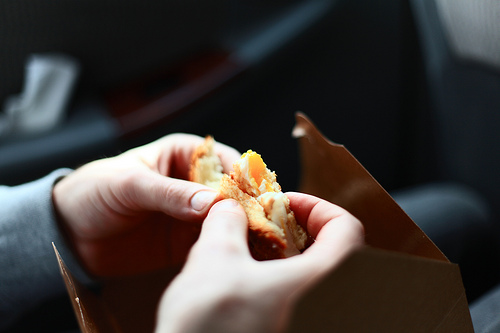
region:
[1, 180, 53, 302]
sleeve for long sleeve shirt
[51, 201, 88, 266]
shadow of sleeve and curved palm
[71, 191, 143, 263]
palm of hand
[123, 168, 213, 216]
thumb that is straight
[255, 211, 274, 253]
edible bread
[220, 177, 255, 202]
burn spot indicating bread was at some point toasted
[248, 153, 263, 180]
yellow substance resembling cheese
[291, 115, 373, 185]
cardboard box used that the sandwich maybe came in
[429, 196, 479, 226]
knees of leg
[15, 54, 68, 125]
items resembles tissue or napkin or white cloth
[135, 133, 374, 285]
food in hand of person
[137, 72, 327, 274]
hands holding food sandwich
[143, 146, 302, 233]
brown and orange sandwich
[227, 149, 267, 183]
orange piece of sandwich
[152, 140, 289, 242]
egg sandwich in hands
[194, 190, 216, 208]
white thumb nail of person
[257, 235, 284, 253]
small white sesame seed on bun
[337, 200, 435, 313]
brown paper bag of food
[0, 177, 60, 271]
grey sweatshirt on person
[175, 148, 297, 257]
half eaten sandwich in hands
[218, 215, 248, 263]
part of a thumb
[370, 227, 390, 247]
edge fo a bag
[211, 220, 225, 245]
part of a thimb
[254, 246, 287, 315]
part of a finger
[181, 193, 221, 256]
par tof a naol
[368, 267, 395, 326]
aprt of a bag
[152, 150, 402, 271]
this is a sandwich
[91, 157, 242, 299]
this is a thumb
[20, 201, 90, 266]
this is a wrist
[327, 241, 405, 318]
this is a paper bag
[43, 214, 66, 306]
this is a jacket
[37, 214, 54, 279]
the jacket is grey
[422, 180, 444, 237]
these are pants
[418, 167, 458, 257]
these are blue jeans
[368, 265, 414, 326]
the bag is brown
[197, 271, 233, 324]
this is a hand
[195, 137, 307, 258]
Food that appears brown and white in color.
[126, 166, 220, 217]
A left hand thumb.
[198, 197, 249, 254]
A right hand thumb.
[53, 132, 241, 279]
The left hand of a person.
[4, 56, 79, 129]
A white tissue sticking out of a box.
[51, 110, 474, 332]
An open brown cardboard box.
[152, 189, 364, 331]
A right hand of a person.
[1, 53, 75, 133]
A white tissue.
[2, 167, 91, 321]
Grey sleeve of someone's shirt.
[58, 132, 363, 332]
Hands of a person holding food.